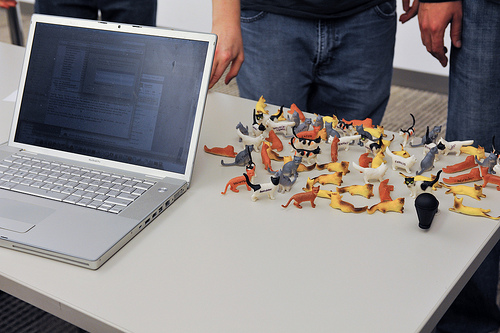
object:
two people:
[203, 0, 499, 154]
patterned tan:
[423, 111, 444, 121]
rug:
[399, 85, 448, 134]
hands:
[202, 24, 241, 88]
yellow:
[357, 189, 367, 197]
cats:
[281, 178, 341, 215]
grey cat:
[279, 160, 298, 185]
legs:
[294, 196, 326, 213]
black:
[423, 196, 433, 215]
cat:
[218, 140, 340, 201]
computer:
[0, 13, 216, 271]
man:
[208, 0, 393, 122]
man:
[412, 0, 499, 155]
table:
[0, 41, 499, 333]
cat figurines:
[202, 95, 500, 228]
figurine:
[219, 167, 257, 198]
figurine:
[241, 171, 281, 201]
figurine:
[317, 189, 373, 209]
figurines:
[288, 128, 322, 165]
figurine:
[234, 128, 267, 150]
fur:
[231, 126, 271, 148]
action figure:
[365, 198, 405, 215]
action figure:
[413, 192, 439, 229]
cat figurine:
[280, 186, 320, 209]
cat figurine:
[242, 173, 280, 202]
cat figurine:
[219, 144, 254, 167]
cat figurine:
[351, 161, 390, 184]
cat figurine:
[447, 195, 500, 220]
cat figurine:
[434, 182, 485, 200]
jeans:
[230, 5, 397, 127]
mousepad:
[0, 200, 49, 234]